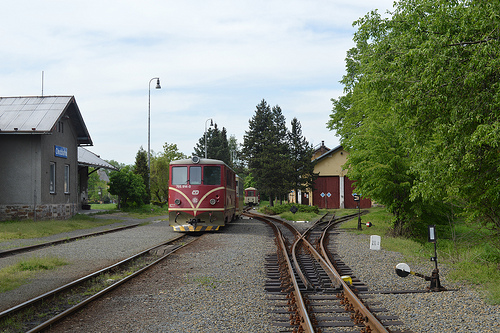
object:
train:
[165, 157, 245, 234]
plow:
[163, 206, 228, 233]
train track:
[235, 207, 398, 331]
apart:
[263, 215, 336, 232]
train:
[242, 186, 258, 206]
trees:
[326, 0, 499, 245]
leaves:
[458, 112, 469, 120]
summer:
[0, 0, 499, 333]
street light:
[145, 78, 160, 178]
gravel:
[35, 213, 300, 332]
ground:
[31, 214, 294, 332]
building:
[0, 94, 93, 219]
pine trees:
[239, 97, 299, 207]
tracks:
[0, 233, 197, 332]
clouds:
[0, 0, 404, 156]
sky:
[0, 0, 405, 167]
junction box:
[393, 225, 444, 294]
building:
[294, 140, 374, 210]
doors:
[308, 173, 327, 209]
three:
[243, 206, 377, 237]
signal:
[393, 262, 412, 280]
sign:
[55, 146, 71, 157]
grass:
[45, 252, 159, 316]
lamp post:
[145, 76, 156, 184]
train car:
[243, 187, 260, 206]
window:
[203, 166, 222, 186]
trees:
[129, 146, 159, 206]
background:
[0, 0, 498, 332]